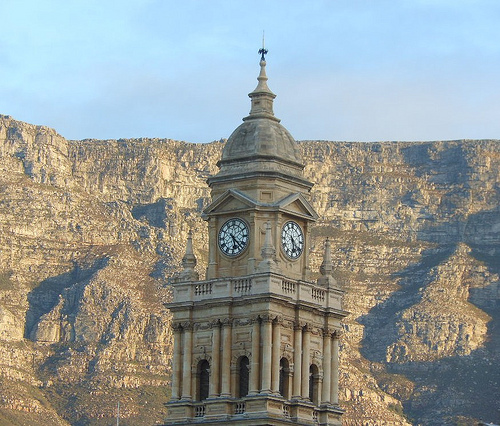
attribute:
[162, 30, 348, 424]
building — brown colored, in sunlight, day lit, rustic brown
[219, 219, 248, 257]
clock — black, white, white colored, showing 5:23, working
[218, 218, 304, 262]
clocks — medium white, medium sized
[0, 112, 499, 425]
mountains — brown faced, brown, rocky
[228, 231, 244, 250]
hands — black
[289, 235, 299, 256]
hands — black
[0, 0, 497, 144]
sky — blue, pale blue, clear blue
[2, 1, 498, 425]
photo — daytime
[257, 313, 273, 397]
pillar — brown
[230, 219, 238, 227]
roman numeral — 12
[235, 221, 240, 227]
roman numeral — 1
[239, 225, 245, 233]
roman numeral — 2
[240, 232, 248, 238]
roman numeral — 3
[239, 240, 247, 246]
roman numeral — 4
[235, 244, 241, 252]
roman numeral — 5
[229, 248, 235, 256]
roman numeral — 6